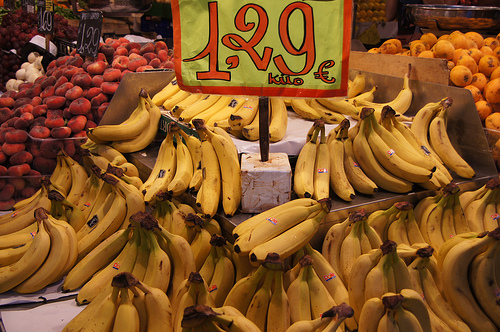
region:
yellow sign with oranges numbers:
[196, 2, 328, 84]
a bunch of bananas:
[234, 203, 325, 267]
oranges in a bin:
[421, 27, 483, 90]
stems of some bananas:
[97, 160, 132, 191]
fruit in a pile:
[39, 59, 93, 119]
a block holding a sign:
[231, 126, 301, 217]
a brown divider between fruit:
[405, 51, 465, 111]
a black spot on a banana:
[150, 161, 175, 188]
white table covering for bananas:
[39, 277, 93, 322]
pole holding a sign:
[244, 85, 279, 158]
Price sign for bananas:
[170, 3, 350, 93]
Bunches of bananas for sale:
[106, 102, 473, 324]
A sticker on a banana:
[85, 211, 100, 226]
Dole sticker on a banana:
[320, 266, 336, 281]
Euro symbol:
[310, 55, 340, 85]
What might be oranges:
[447, 26, 492, 81]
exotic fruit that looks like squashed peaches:
[46, 60, 96, 115]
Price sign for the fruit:
[75, 5, 95, 55]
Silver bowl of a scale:
[405, 0, 495, 25]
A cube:
[235, 146, 290, 208]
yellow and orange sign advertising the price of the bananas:
[161, 0, 361, 100]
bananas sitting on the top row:
[157, 64, 416, 125]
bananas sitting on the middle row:
[112, 99, 468, 196]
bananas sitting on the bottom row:
[25, 176, 496, 326]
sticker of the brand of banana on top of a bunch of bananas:
[318, 267, 338, 287]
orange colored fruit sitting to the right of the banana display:
[379, 24, 497, 114]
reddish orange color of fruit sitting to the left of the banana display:
[18, 45, 84, 147]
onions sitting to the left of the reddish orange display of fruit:
[6, 49, 45, 93]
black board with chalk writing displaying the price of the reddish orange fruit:
[77, 7, 104, 64]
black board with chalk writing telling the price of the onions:
[30, 4, 57, 38]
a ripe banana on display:
[209, 123, 239, 216]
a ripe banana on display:
[198, 131, 219, 220]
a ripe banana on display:
[173, 130, 193, 199]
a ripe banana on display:
[143, 137, 174, 204]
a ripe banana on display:
[294, 131, 316, 203]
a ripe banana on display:
[317, 140, 332, 205]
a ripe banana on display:
[363, 126, 432, 186]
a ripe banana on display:
[417, 260, 465, 327]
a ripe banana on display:
[236, 204, 314, 249]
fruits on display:
[3, 2, 497, 327]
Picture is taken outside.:
[35, 15, 468, 300]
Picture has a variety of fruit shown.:
[57, 49, 467, 292]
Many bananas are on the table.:
[48, 72, 471, 317]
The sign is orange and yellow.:
[189, 7, 361, 113]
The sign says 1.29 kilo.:
[187, 10, 375, 127]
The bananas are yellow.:
[80, 112, 445, 295]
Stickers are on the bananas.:
[219, 208, 301, 263]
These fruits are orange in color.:
[421, 35, 496, 127]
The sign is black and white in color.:
[60, 5, 125, 76]